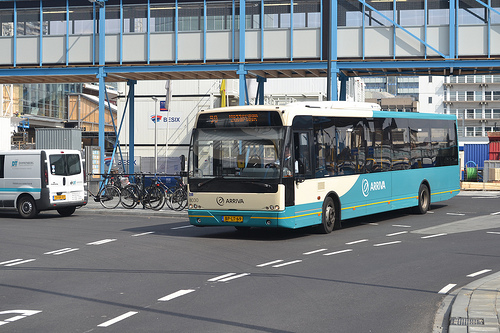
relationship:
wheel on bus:
[318, 191, 344, 232] [182, 104, 468, 229]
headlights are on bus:
[183, 199, 283, 237] [182, 104, 468, 229]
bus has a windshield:
[182, 104, 468, 229] [191, 123, 287, 185]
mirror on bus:
[174, 150, 190, 185] [182, 104, 468, 229]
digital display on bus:
[199, 112, 266, 130] [182, 104, 468, 229]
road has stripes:
[9, 179, 498, 326] [77, 228, 440, 328]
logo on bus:
[355, 178, 374, 206] [182, 104, 468, 229]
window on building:
[20, 83, 73, 115] [4, 11, 118, 185]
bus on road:
[182, 104, 468, 229] [9, 179, 498, 326]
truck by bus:
[1, 145, 92, 221] [182, 104, 468, 229]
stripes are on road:
[77, 228, 440, 328] [9, 179, 498, 326]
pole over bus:
[323, 68, 346, 106] [182, 104, 468, 229]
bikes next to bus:
[89, 168, 197, 212] [182, 104, 468, 229]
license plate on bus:
[215, 214, 248, 228] [182, 104, 468, 229]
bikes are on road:
[89, 168, 197, 212] [9, 179, 498, 326]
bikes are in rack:
[89, 168, 197, 212] [83, 171, 189, 193]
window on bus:
[302, 121, 460, 167] [182, 104, 468, 229]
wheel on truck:
[16, 195, 45, 219] [1, 145, 92, 221]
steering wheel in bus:
[261, 157, 285, 177] [182, 104, 468, 229]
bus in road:
[182, 104, 468, 229] [9, 179, 498, 326]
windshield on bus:
[191, 123, 287, 185] [182, 104, 468, 229]